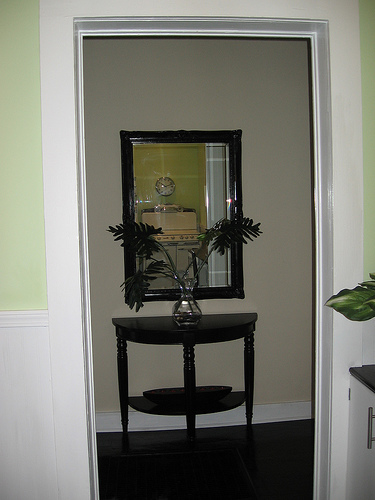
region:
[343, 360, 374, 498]
a small white refrigerator.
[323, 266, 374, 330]
a big green plant leaf.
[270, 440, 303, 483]
a black shinny floor.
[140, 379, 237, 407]
a long black bowl on the shelf.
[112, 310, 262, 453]
a small black stand.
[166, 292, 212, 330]
a little small clear vase.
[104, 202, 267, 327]
a vase with flowers inside.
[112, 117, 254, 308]
a dark brown mirror on the wall.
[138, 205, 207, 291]
a all white stove.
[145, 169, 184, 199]
a round grey clock.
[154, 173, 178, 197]
Reflection of silver clock in mirror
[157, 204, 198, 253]
Reflection in mirror of white stove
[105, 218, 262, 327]
Plant clippings in clear vase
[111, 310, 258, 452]
Two level shelf in half circle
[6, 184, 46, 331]
Pale green wall with white border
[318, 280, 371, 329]
Large green leaf against white door frame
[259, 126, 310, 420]
Pale yellow wall with white floor board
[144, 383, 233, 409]
Long shallow bowl on shelf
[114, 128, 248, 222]
Mirror with dark wooden frame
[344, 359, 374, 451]
White cabinet with silver handle and black counter top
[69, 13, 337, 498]
Doorway in the center of the wall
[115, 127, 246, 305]
Mirror with a brown frame on the wall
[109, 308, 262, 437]
Brown wooden table under the mirror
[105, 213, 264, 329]
Vase with flowering plants on the table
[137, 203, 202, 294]
Reflection of old stove in the mirror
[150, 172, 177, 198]
Reflection of wall clock in the mirror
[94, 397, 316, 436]
White baseboard on the wall behind the table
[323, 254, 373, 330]
Green leaf to the right of the doorway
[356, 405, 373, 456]
Cabinet handle on the cabinet to the right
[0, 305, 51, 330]
Chair molding in the center of the wall to the left of the doorway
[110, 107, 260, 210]
mirror on a wall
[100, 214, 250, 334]
vase of green flowers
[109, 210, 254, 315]
vase of flowers on table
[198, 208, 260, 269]
flower in a vase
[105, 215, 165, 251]
flower in a vase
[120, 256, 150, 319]
flower in a vase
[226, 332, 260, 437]
leg of a table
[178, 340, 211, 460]
leg of a table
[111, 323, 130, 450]
leg of a table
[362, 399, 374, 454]
handle of a cabinet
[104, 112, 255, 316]
a mirror on the wall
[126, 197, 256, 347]
a clear vase with tall flowers in it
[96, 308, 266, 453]
a wood table under a mirror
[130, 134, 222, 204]
a reflection of a clock in a mirror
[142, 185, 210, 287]
a reflection of a stove in a mirror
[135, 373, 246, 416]
a bowl on a table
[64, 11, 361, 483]
a white door frame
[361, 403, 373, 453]
a silver cabinet door handle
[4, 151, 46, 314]
a wall painted light green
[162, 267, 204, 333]
a clear flower vase